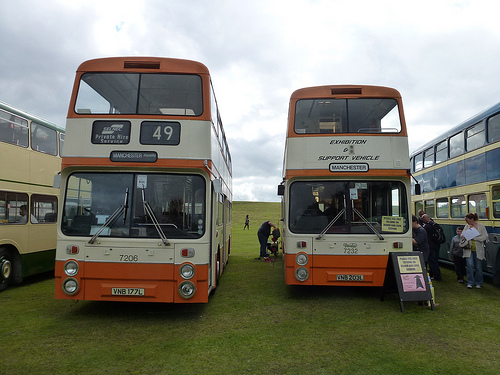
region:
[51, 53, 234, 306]
white and orange bus on the left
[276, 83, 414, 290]
orange and white bus on the right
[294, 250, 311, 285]
headlights on the bus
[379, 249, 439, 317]
black sign in front of the bus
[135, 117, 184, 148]
black sign with white numbers on the bus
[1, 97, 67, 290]
cream and black bus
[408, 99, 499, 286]
blue and yellow bus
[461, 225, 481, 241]
white paper in the woman's hand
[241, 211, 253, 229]
person behind the busses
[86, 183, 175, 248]
wipers on the bus windshield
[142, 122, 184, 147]
The number on the bus.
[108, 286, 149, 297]
The yellow license plate.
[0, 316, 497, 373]
A green grassy ground.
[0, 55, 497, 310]
Four double decker buses.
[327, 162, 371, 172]
The destination sign on the bus.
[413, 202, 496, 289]
A group of people.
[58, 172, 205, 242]
The window of the bus.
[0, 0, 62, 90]
A patch of dark clouds.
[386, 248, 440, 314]
A sign outside of the bus.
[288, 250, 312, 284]
The lights on the bus.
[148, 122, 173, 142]
number on the bus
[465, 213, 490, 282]
a person standing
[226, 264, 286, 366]
the grass is short and green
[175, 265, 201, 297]
headlights on the bus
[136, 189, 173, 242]
windshield wiper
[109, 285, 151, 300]
license plate on the bus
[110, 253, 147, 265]
number on the bus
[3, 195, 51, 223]
windows on the bus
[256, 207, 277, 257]
a person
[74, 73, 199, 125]
a windshield on the bus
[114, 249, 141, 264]
The numbers seven,two,zero and six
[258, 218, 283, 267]
A guy standing alone beside the bus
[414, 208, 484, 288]
A group of people standing together beside the bus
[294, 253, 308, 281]
The headlights on the bus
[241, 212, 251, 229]
A person standing out in a feild alone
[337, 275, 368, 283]
The license plate on the bus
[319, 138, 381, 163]
The name of the bus line on the orange bus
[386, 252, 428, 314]
The small billboard in front of the orange bus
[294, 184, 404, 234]
The wind sheild on the bus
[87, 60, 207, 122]
The second story of the double decker bus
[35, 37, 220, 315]
an orange and white double decker bus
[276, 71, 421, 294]
an orange and white double decker bus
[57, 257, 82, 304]
two round shiny headlights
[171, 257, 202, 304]
two round shiny headlights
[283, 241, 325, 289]
two round shiny headlights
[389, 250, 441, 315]
a black board with pink and yellow signs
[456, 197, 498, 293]
a woman holding a paper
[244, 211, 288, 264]
a man pouring a charcoal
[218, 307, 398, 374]
green grass in the front of the bus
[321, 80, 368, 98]
a vent on the bust roof